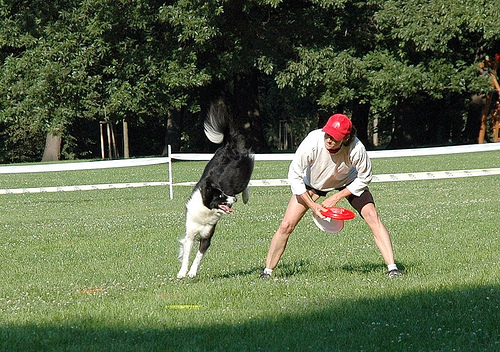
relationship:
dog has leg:
[175, 96, 255, 279] [178, 223, 191, 280]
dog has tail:
[175, 96, 255, 279] [203, 96, 248, 151]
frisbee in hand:
[321, 207, 356, 221] [309, 203, 330, 219]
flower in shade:
[376, 295, 500, 351] [3, 282, 500, 352]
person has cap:
[258, 113, 405, 277] [319, 112, 353, 143]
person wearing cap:
[258, 113, 405, 277] [319, 112, 353, 143]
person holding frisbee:
[258, 113, 405, 277] [321, 207, 356, 221]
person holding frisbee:
[258, 113, 405, 277] [314, 212, 345, 236]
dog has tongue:
[175, 96, 255, 279] [221, 203, 234, 212]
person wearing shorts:
[258, 113, 405, 277] [303, 183, 375, 219]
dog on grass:
[175, 96, 255, 279] [0, 146, 499, 352]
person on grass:
[258, 113, 405, 277] [0, 146, 499, 352]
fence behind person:
[1, 143, 499, 195] [258, 113, 405, 277]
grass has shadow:
[0, 146, 499, 352] [1, 282, 497, 350]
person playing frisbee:
[258, 113, 405, 277] [321, 207, 356, 221]